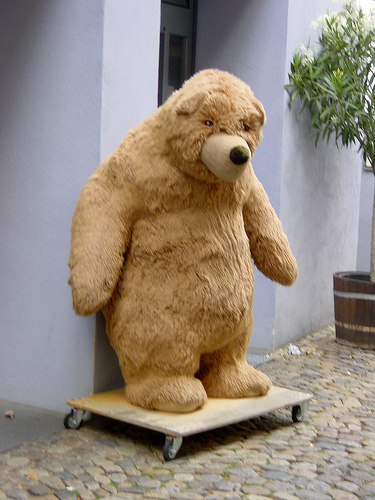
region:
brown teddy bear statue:
[81, 61, 294, 366]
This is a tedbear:
[70, 62, 310, 418]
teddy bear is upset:
[148, 56, 266, 214]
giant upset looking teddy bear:
[61, 52, 325, 447]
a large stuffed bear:
[77, 136, 281, 415]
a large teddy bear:
[97, 172, 292, 416]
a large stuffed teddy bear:
[88, 152, 251, 381]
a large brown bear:
[84, 147, 283, 420]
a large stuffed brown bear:
[71, 137, 353, 496]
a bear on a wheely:
[92, 165, 373, 476]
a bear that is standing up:
[26, 149, 366, 469]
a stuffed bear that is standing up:
[86, 192, 268, 442]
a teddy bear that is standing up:
[105, 180, 368, 474]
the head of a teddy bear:
[170, 92, 279, 213]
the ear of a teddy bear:
[163, 85, 233, 123]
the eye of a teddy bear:
[187, 90, 248, 134]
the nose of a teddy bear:
[217, 132, 268, 164]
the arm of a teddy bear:
[61, 153, 154, 318]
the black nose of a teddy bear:
[214, 125, 268, 187]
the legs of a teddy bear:
[127, 313, 280, 427]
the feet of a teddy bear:
[118, 333, 270, 433]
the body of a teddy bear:
[117, 101, 305, 405]